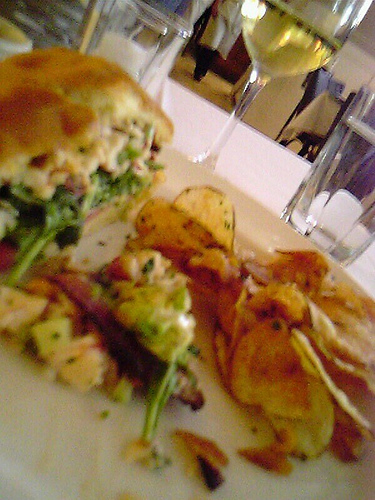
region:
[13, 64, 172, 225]
a food item in plate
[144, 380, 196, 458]
a small stem of food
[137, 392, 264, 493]
a piece fallen table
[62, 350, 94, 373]
a black mark in food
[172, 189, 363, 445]
a group of chips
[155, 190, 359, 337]
a series of chips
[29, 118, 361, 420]
a group of eatable items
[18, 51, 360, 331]
a group of food items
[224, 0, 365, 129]
a glass with wine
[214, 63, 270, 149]
white stand of the glass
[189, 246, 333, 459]
these are homemade chips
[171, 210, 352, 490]
these are spiced potato chips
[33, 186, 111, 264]
this is a sandwich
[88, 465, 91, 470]
this is a plate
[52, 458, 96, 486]
the plate is white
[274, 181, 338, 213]
this is a glass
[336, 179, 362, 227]
the glass is clear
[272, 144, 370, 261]
the glass has water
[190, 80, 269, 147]
this is a large glass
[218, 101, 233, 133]
the glass has a long handle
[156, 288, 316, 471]
this is a plate of food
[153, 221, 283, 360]
these are sliced potatoes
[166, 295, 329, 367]
the potatoes are crisp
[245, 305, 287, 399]
the potatoes are yellow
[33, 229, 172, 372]
this is a sandwich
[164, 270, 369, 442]
this is a handful of chips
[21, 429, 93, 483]
this is a plate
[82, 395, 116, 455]
the plate is white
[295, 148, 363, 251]
this is a glass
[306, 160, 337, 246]
the glass has water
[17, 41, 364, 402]
the food on the plate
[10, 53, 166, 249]
the sandwich on the plate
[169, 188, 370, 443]
the potato chips on the plate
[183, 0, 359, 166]
the glass of wine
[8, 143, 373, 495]
the plate is white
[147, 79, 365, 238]
the table cloth is white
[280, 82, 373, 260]
the glass of water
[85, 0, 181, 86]
the glass on the table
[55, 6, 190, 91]
the glass is empty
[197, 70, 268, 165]
stem of the glass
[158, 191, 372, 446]
the chips on the plate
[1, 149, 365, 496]
the plate on the table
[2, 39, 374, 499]
food on the table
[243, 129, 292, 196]
the tablecloth is white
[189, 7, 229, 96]
the person wearing the apron